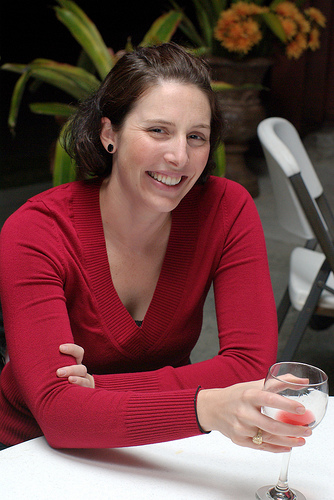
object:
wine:
[271, 406, 318, 441]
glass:
[254, 360, 329, 500]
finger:
[57, 341, 84, 365]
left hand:
[51, 341, 95, 390]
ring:
[248, 425, 266, 448]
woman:
[1, 39, 315, 456]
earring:
[105, 143, 115, 154]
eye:
[146, 124, 170, 138]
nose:
[162, 130, 192, 172]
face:
[119, 77, 213, 214]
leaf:
[47, 5, 112, 82]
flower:
[303, 6, 332, 29]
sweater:
[0, 172, 281, 456]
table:
[0, 372, 333, 499]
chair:
[254, 115, 333, 375]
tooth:
[160, 173, 169, 185]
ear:
[95, 114, 119, 156]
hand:
[211, 371, 316, 455]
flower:
[285, 32, 308, 61]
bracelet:
[192, 384, 211, 435]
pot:
[196, 52, 266, 201]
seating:
[288, 243, 333, 318]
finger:
[241, 421, 305, 450]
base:
[256, 483, 310, 499]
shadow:
[31, 434, 333, 499]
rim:
[269, 360, 329, 388]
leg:
[278, 312, 320, 380]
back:
[254, 114, 330, 243]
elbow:
[29, 370, 96, 454]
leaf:
[27, 99, 80, 117]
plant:
[1, 0, 249, 175]